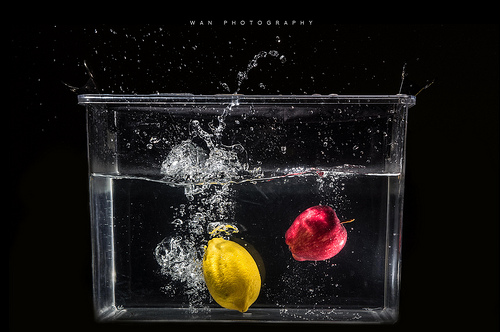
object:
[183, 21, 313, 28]
name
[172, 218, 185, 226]
bubbles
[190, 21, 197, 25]
letter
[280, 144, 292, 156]
bubbles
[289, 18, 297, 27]
white letter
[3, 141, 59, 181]
black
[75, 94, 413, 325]
bowl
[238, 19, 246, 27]
letter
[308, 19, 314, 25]
letter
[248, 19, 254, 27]
letter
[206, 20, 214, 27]
letter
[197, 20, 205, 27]
white letter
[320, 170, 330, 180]
spots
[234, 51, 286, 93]
water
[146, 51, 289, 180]
water splash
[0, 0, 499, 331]
background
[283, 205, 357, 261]
apple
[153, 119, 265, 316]
splash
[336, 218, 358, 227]
stem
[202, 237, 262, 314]
lemon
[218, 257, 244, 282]
yellow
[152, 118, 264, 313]
splashed water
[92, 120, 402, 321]
water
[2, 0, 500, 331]
photo